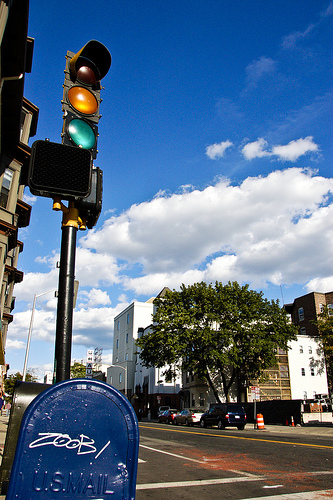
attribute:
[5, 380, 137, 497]
post box — blue, small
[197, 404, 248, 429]
car — parked, black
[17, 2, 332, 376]
sky — blue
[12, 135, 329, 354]
clouds — white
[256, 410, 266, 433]
traffic cone — orange, small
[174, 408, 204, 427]
car — gray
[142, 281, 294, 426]
tree — gorgeous, green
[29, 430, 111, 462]
graffiti — white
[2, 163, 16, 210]
window — open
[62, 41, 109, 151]
light — on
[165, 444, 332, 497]
dirt — red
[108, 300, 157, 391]
building — white